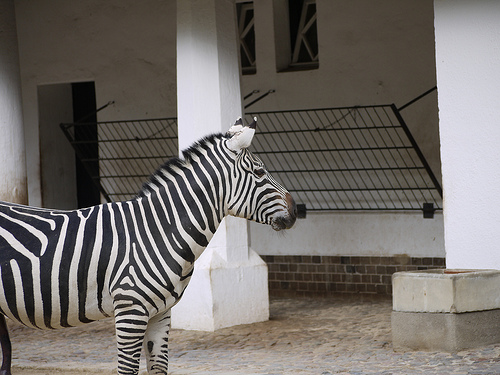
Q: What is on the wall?
A: A metal grate.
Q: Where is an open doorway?
A: Left of the grate.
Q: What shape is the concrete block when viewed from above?
A: Square.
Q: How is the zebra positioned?
A: Facing right.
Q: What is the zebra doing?
A: Standing.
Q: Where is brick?
A: At the base of the wall.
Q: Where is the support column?
A: Behind the zebra's head.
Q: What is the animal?
A: A zebra.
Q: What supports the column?
A: Concrete blocks.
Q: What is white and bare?
A: The ground.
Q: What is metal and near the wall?
A: The cage.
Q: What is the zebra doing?
A: Standing.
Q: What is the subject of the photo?
A: Animal.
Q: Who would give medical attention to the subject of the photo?
A: Veterinarian.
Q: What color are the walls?
A: White.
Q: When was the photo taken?
A: Daytime.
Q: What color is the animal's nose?
A: Black.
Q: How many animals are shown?
A: One.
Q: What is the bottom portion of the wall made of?
A: Brick.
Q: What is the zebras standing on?
A: Dirt.